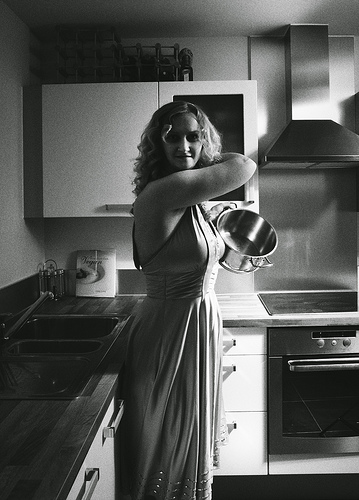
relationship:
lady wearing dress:
[122, 101, 258, 499] [127, 203, 227, 500]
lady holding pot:
[122, 101, 258, 499] [216, 203, 279, 275]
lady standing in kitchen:
[122, 101, 258, 499] [0, 1, 358, 499]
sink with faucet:
[0, 312, 131, 401] [0, 291, 54, 344]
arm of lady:
[133, 152, 257, 210] [122, 101, 258, 499]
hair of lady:
[130, 100, 221, 214] [122, 101, 258, 499]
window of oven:
[283, 353, 358, 439] [268, 326, 359, 455]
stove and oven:
[258, 291, 358, 316] [268, 326, 359, 455]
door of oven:
[280, 353, 357, 437] [268, 326, 359, 455]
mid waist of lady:
[144, 270, 216, 305] [122, 101, 258, 499]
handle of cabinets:
[105, 203, 135, 214] [40, 80, 258, 220]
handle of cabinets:
[248, 176, 255, 204] [40, 80, 258, 220]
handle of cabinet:
[83, 467, 101, 499] [68, 431, 103, 500]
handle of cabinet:
[104, 398, 128, 441] [99, 388, 124, 500]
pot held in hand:
[216, 203, 279, 275] [206, 202, 236, 218]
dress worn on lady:
[127, 203, 227, 500] [122, 101, 258, 499]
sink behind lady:
[0, 312, 131, 401] [122, 101, 258, 499]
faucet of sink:
[0, 291, 54, 344] [0, 312, 131, 401]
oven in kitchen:
[268, 326, 359, 455] [0, 1, 358, 499]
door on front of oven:
[280, 353, 357, 437] [268, 326, 359, 455]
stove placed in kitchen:
[258, 291, 358, 316] [0, 1, 358, 499]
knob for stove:
[317, 339, 324, 347] [258, 291, 358, 316]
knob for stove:
[341, 338, 353, 348] [258, 291, 358, 316]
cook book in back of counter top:
[75, 250, 119, 301] [0, 289, 358, 498]